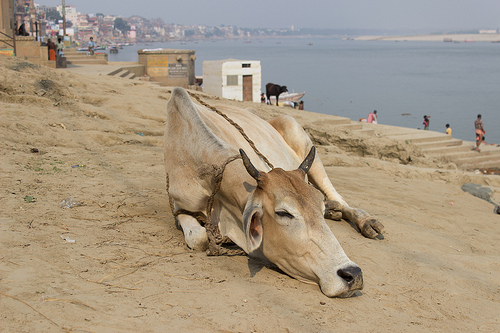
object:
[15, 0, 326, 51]
buildings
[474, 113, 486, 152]
person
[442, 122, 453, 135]
person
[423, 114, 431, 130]
person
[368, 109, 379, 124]
person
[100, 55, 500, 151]
river bank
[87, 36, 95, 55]
person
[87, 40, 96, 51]
shirt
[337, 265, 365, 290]
nose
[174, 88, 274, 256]
rope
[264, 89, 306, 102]
boat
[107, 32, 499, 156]
water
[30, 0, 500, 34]
sky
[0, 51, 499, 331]
dirt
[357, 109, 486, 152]
people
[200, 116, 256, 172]
fur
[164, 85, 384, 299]
animal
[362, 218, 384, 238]
hoof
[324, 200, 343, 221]
hoof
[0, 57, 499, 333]
sand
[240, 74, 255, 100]
door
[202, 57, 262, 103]
building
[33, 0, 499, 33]
clouds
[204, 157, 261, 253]
neck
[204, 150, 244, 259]
rope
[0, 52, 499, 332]
ground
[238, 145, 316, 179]
horns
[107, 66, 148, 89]
steps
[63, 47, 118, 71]
steps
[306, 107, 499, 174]
steps